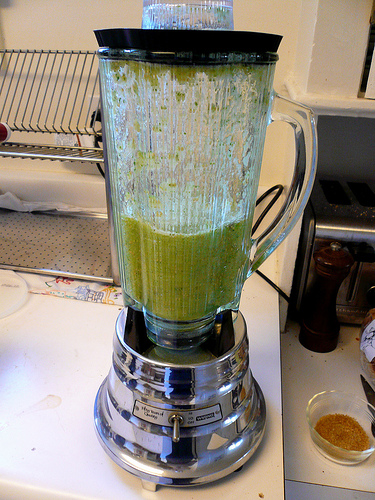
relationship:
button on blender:
[168, 415, 185, 446] [93, 0, 319, 489]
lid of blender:
[93, 4, 286, 57] [93, 0, 319, 489]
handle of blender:
[244, 90, 322, 285] [93, 0, 319, 489]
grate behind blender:
[0, 43, 103, 174] [93, 0, 319, 489]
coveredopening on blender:
[142, 1, 234, 28] [93, 0, 319, 489]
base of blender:
[94, 322, 270, 489] [93, 0, 319, 489]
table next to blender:
[280, 282, 373, 496] [93, 0, 319, 489]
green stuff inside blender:
[117, 216, 249, 320] [93, 0, 319, 489]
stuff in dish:
[316, 413, 369, 460] [296, 377, 373, 476]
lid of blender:
[93, 0, 285, 57] [81, 1, 329, 396]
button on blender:
[152, 406, 199, 453] [93, 0, 319, 489]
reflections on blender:
[95, 307, 266, 486] [93, 0, 319, 489]